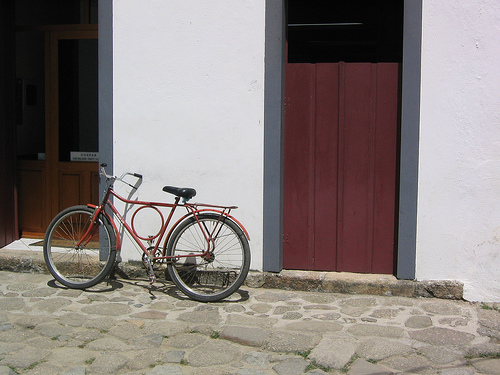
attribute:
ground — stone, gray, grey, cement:
[1, 249, 500, 372]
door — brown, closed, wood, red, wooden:
[259, 1, 431, 284]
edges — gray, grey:
[398, 0, 418, 282]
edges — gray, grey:
[258, 1, 288, 277]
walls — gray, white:
[113, 5, 267, 275]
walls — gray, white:
[415, 2, 499, 283]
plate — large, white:
[67, 148, 102, 170]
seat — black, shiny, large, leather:
[161, 184, 199, 202]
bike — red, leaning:
[29, 156, 257, 307]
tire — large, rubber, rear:
[162, 209, 255, 305]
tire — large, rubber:
[40, 201, 121, 290]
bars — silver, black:
[99, 161, 144, 185]